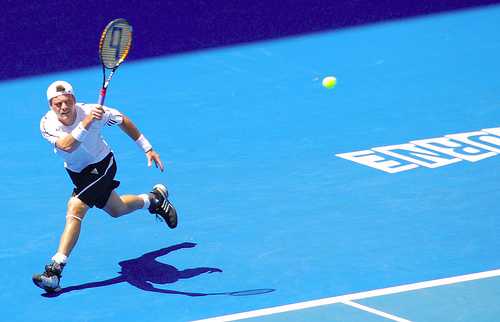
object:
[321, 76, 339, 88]
ball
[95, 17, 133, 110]
racket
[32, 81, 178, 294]
man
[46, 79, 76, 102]
cap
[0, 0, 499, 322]
ground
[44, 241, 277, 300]
shadow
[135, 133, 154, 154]
band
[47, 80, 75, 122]
head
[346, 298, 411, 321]
line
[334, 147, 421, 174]
letters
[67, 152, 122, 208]
shorts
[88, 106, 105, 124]
hand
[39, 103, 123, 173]
shirt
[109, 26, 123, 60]
logo